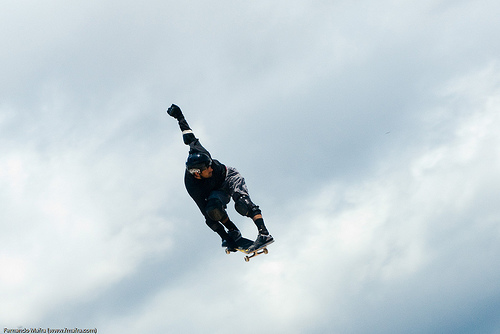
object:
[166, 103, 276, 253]
skateboarder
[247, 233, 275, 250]
shoe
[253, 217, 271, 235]
sock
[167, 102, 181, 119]
glove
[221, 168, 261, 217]
pants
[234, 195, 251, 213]
knee pad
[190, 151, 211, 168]
helmet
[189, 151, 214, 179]
head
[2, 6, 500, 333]
sky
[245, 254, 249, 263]
wheel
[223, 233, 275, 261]
skateboard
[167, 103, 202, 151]
arm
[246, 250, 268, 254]
arm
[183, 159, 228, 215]
shirt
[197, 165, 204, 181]
chin strap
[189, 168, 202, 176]
writing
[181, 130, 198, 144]
elbow pad